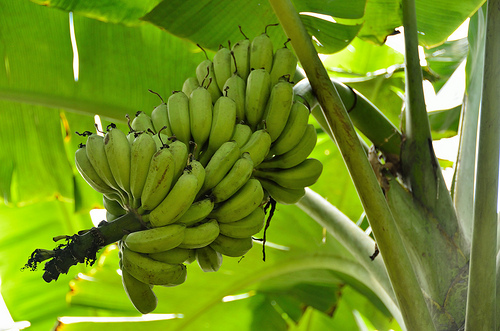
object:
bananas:
[102, 120, 135, 212]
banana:
[122, 252, 186, 289]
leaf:
[29, 0, 374, 66]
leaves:
[327, 2, 489, 49]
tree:
[267, 0, 497, 329]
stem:
[28, 218, 139, 280]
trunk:
[386, 150, 470, 330]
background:
[2, 0, 499, 230]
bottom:
[122, 111, 320, 295]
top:
[74, 31, 273, 184]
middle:
[149, 71, 278, 217]